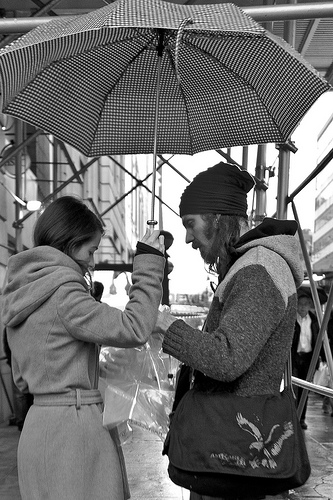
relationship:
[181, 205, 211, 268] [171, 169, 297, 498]
face of man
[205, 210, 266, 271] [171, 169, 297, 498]
hair of man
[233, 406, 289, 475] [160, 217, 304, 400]
eagle on hoodie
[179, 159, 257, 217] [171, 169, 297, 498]
beanie on man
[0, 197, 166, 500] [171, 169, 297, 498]
person with bohemian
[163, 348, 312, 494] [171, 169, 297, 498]
bag of man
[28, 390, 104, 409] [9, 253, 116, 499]
belt on coat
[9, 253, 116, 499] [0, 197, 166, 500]
coat of person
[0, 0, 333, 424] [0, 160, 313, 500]
construction pylon above couple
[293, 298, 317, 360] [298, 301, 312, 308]
man wearing glasses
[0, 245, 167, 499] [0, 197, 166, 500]
coat of person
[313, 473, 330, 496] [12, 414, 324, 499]
crack in tarmac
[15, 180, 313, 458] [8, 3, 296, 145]
couple under umbrella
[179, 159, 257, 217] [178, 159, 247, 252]
beanie on head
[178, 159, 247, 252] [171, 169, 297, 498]
head of man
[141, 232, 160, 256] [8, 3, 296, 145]
hand holding umbrella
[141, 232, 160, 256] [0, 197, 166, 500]
hand of person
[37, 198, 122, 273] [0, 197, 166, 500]
head of person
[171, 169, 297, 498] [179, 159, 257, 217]
man with beanie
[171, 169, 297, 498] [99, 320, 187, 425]
man holding plastic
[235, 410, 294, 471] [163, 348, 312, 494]
eagle on bag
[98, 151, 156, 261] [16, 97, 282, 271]
building behind construction pylon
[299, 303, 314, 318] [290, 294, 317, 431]
face of man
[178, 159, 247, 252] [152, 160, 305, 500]
head of man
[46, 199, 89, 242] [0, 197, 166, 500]
hair of person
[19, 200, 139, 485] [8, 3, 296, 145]
person holding umbrella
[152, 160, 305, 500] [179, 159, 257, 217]
man wearing beanie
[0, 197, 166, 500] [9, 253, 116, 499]
person wearing coat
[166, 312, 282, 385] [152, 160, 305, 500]
arm of man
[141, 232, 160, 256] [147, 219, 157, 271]
hand holding handle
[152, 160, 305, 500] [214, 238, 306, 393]
man wearing hoodie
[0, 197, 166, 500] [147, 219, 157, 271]
person holding handle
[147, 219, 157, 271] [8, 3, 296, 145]
handle of umbrella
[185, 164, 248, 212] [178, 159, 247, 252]
beanie on head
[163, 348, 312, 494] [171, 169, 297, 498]
bag held by man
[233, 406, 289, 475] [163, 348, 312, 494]
eagle on bag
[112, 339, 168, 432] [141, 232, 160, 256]
bag in hand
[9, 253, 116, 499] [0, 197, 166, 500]
coat on person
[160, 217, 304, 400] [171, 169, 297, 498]
hoodie on man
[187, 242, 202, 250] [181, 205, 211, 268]
mustache on face